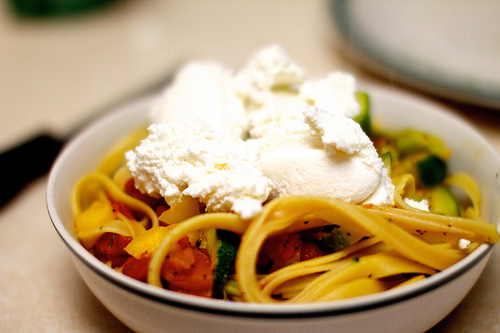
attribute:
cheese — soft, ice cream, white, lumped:
[164, 77, 353, 197]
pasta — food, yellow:
[367, 243, 412, 265]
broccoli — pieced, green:
[407, 149, 441, 187]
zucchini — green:
[214, 232, 238, 293]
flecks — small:
[338, 239, 389, 287]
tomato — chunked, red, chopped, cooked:
[149, 246, 208, 289]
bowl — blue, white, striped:
[429, 295, 464, 306]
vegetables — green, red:
[89, 200, 261, 293]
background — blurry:
[254, 20, 313, 41]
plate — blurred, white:
[378, 37, 452, 75]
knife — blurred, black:
[13, 108, 146, 135]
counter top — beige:
[18, 211, 42, 266]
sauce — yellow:
[464, 137, 495, 167]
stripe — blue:
[418, 279, 442, 286]